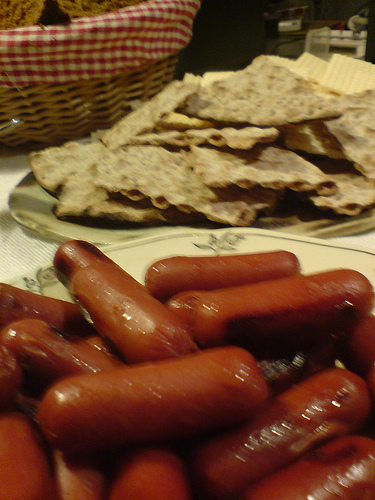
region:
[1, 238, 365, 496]
Pile of little smokey's on a plate.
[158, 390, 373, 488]
Light reflecting on sausage links.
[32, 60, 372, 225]
Tortilla chips on a platter.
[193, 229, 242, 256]
Flower design on platter.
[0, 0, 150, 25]
Bread inside a basket.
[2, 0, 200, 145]
A basket with bread in it.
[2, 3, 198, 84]
Red and white cloth in basket.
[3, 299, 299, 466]
Oil on sausage links.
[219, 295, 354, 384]
Burn spots on links.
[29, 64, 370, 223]
Pile of whole grain tortilla chips.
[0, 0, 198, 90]
basket cloth is red and white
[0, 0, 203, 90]
cloth is plaid patterned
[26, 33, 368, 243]
sun chips on the plate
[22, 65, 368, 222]
the sun chips are brown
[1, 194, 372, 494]
hot dogs on the table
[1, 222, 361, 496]
the hot dogs are brown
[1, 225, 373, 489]
the hot dogs are wet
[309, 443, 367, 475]
black spot on the hot dog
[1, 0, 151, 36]
bread on the basket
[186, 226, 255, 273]
green leaf design on the table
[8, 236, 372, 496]
hot dog on plate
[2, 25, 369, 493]
food on table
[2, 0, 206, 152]
basket with red and white paper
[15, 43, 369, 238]
tortilla on plate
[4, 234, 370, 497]
sausage link on plate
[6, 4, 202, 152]
bread is in basket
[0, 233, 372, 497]
plate is white with flowers on it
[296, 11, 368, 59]
white chair is in far end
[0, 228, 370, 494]
sausage are fully cooked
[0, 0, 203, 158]
basket is tan in color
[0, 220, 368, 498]
wieners on a plate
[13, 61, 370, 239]
chips on a plate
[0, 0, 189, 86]
a red white checkered cloth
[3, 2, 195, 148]
a basket with a red and white cloth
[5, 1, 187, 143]
bread in a basket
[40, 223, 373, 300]
a silver and white plate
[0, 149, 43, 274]
a white table cloth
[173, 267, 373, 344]
a burnt wiener on a plate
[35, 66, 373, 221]
brown bread chips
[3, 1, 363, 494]
a table with food on it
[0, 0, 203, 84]
Cloth on basket is red and white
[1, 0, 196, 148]
Basket next to plate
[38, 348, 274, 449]
Sausage on top of sausage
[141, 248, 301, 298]
Sausage on top of sausage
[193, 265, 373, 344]
Sausage on top of sausage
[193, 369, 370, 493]
Sausage on top of sausage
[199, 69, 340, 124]
Chip on top of chip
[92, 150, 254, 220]
Chip on top of chip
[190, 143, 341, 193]
Chip on top of chip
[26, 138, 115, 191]
Chip on top of chip